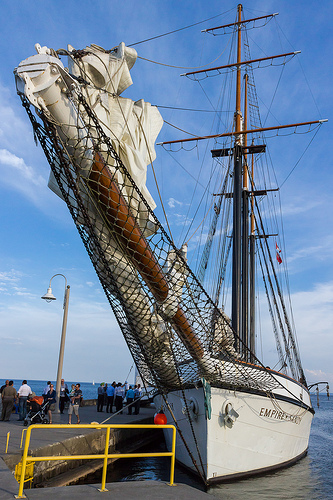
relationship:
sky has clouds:
[0, 0, 331, 393] [0, 81, 331, 394]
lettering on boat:
[258, 408, 303, 423] [13, 1, 317, 487]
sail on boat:
[154, 2, 328, 391] [13, 1, 317, 487]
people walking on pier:
[0, 378, 144, 427] [0, 396, 160, 488]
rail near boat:
[16, 419, 177, 498] [13, 1, 317, 487]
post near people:
[48, 283, 70, 412] [0, 378, 141, 422]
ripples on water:
[214, 416, 331, 498] [74, 390, 331, 498]